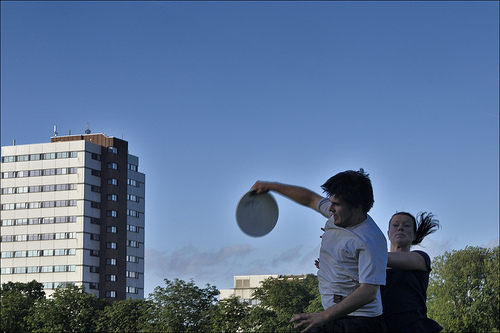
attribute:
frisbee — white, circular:
[233, 188, 282, 239]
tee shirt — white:
[314, 191, 389, 318]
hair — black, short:
[319, 167, 377, 215]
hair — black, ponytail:
[387, 208, 443, 247]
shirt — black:
[362, 249, 447, 332]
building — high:
[0, 120, 151, 302]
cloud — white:
[223, 244, 247, 257]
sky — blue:
[2, 2, 499, 301]